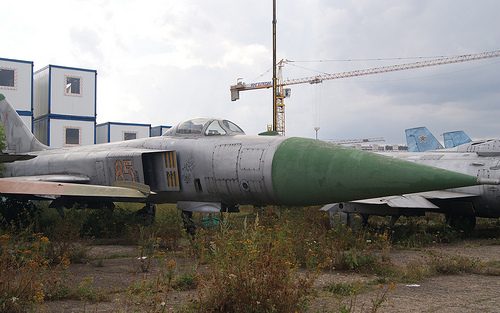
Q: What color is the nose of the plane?
A: Green.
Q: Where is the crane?
A: Behind the planes.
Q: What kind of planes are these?
A: Jets.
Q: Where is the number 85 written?
A: On the side of the jet.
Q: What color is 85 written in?
A: Orange.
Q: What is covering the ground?
A: Vegetation.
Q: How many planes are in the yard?
A: Three.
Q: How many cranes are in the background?
A: One.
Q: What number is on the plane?
A: 85.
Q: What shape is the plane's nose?
A: Cone.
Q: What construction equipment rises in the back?
A: Crane.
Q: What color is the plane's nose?
A: Green.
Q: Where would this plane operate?
A: Sky.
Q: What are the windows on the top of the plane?
A: Cockpit.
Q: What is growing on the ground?
A: Weeds.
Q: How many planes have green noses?
A: 1.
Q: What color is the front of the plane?
A: Green.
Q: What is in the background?
A: Clouds.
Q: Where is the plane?
A: In a field.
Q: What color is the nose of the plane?
A: Green.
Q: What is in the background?
A: A crane.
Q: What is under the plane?
A: Flowers.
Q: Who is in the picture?
A: No one.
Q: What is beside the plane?
A: Another plane.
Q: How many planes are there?
A: Two.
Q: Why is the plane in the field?
A: It's not being used anymore.